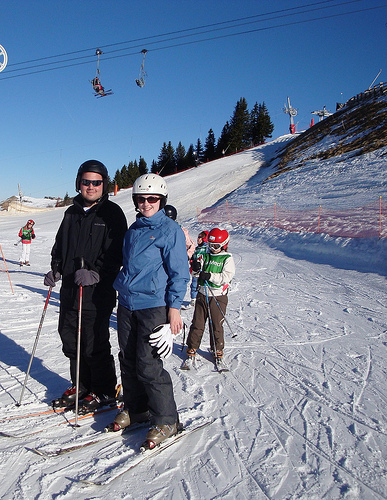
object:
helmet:
[75, 157, 110, 199]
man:
[45, 159, 128, 412]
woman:
[112, 172, 190, 449]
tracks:
[6, 258, 385, 498]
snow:
[3, 126, 383, 499]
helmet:
[133, 169, 168, 201]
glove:
[149, 323, 175, 358]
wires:
[0, 2, 384, 86]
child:
[179, 225, 235, 370]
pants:
[19, 237, 34, 263]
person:
[16, 218, 35, 265]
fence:
[196, 204, 387, 238]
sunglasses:
[75, 177, 102, 187]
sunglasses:
[132, 195, 159, 202]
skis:
[0, 402, 73, 436]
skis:
[27, 410, 212, 482]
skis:
[176, 355, 232, 372]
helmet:
[208, 227, 226, 245]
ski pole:
[73, 253, 87, 424]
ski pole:
[15, 272, 57, 405]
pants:
[185, 291, 228, 357]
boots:
[111, 410, 181, 449]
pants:
[116, 296, 181, 425]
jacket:
[118, 211, 191, 309]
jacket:
[51, 192, 128, 287]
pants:
[58, 283, 116, 394]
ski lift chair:
[87, 72, 112, 99]